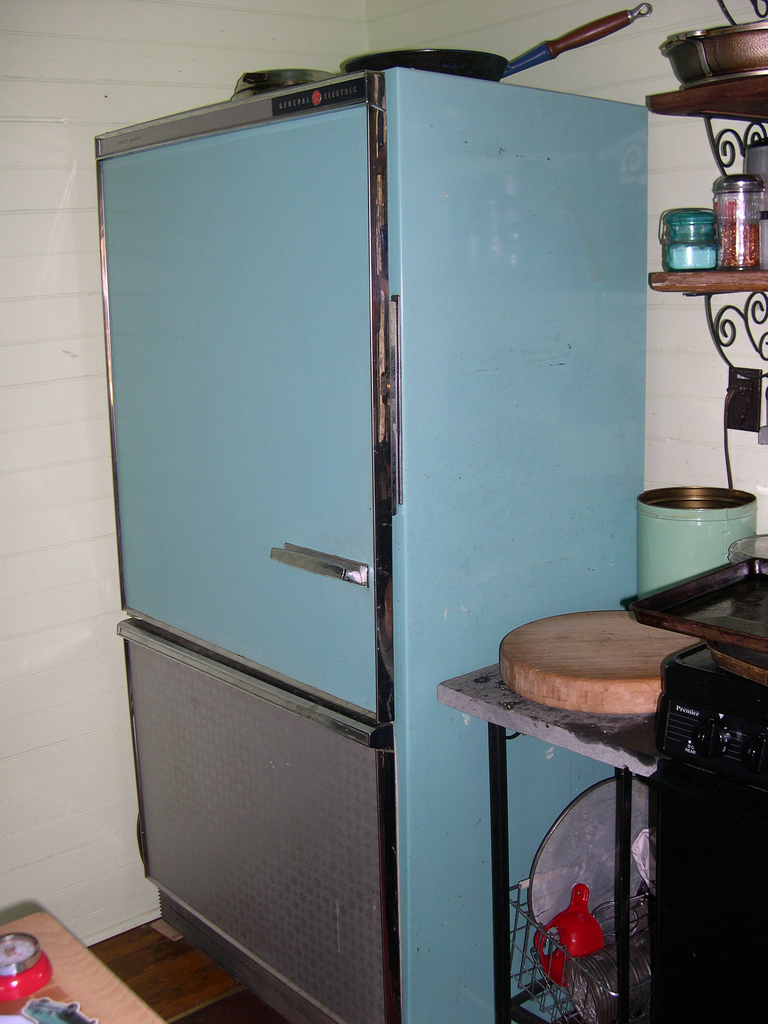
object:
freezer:
[119, 619, 401, 1022]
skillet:
[345, 48, 509, 82]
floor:
[85, 914, 288, 1023]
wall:
[2, 2, 766, 947]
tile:
[0, 331, 111, 390]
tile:
[0, 534, 118, 640]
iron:
[514, 905, 530, 953]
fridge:
[91, 59, 644, 1023]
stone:
[151, 919, 184, 942]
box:
[664, 209, 718, 270]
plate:
[531, 775, 650, 940]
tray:
[499, 611, 702, 714]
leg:
[648, 786, 659, 1020]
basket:
[510, 879, 651, 1020]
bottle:
[714, 174, 759, 266]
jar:
[637, 486, 757, 603]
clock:
[1, 932, 40, 977]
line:
[404, 724, 415, 1015]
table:
[438, 664, 657, 1023]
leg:
[488, 719, 510, 1021]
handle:
[269, 541, 367, 586]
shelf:
[647, 271, 755, 291]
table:
[0, 899, 172, 1023]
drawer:
[94, 71, 390, 719]